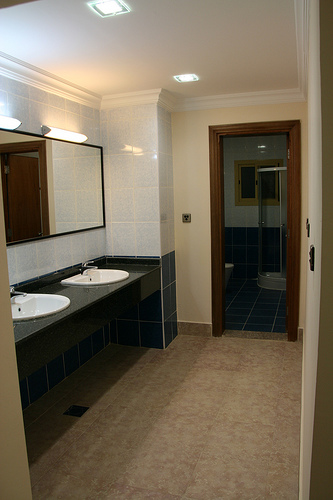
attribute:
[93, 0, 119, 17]
light — square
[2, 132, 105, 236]
mirror — black framed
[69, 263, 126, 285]
sink — white, silver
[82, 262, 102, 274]
faucet — silver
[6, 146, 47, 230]
door reflection — wooden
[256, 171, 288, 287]
shower — circular, clear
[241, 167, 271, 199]
window — yellow, yellow framed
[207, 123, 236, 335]
door frame — wooden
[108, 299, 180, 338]
tiles on wall — blue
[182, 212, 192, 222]
light switch — black, silver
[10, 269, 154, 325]
counter — granite, black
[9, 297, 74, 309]
sink — white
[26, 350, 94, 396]
tile under counter — black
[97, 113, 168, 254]
tile next to mirror — white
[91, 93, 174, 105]
crown molding — white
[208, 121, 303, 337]
doorway — wooden